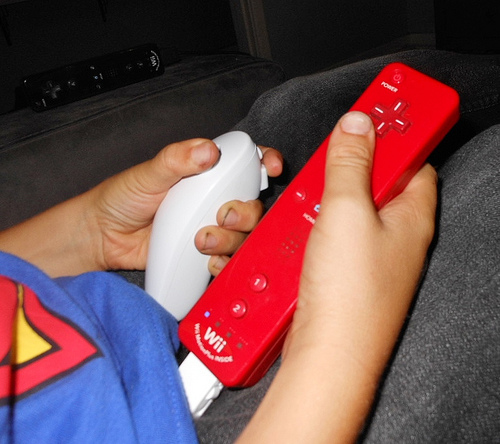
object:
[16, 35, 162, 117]
wii remote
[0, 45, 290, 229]
arm of chair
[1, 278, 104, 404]
superman logo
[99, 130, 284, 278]
hand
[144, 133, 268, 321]
wii remote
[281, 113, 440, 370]
hand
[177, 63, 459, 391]
wii remote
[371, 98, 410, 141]
directional button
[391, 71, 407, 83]
power button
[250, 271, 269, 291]
1 botton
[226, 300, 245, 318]
2 button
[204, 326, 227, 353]
wii logo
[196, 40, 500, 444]
jeans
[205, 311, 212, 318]
light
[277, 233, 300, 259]
speaker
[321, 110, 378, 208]
thumb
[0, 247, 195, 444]
hem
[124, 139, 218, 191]
thumb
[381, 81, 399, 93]
power